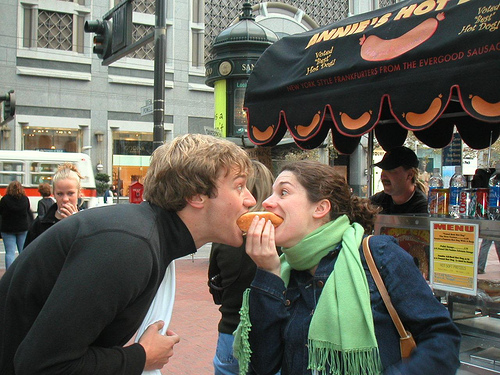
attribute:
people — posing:
[1, 134, 462, 374]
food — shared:
[237, 212, 284, 233]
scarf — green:
[231, 214, 382, 373]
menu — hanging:
[429, 221, 479, 297]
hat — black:
[368, 144, 418, 169]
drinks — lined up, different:
[428, 165, 499, 220]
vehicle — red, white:
[1, 150, 98, 220]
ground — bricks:
[0, 257, 222, 374]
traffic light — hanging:
[83, 18, 105, 55]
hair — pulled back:
[279, 160, 384, 234]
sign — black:
[112, 140, 153, 157]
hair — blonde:
[145, 133, 253, 207]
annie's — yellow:
[305, 12, 391, 47]